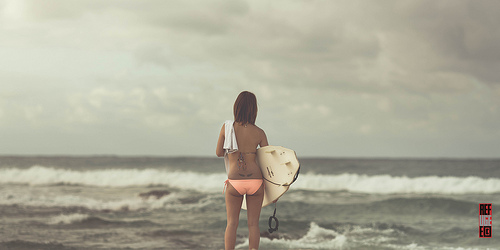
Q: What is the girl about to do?
A: Surf.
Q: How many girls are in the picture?
A: 1.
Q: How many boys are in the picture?
A: 0.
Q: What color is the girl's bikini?
A: Pink.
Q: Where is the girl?
A: Beach.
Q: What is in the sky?
A: Clouds.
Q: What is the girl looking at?
A: Ocean.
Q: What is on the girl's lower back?
A: Tattoo.